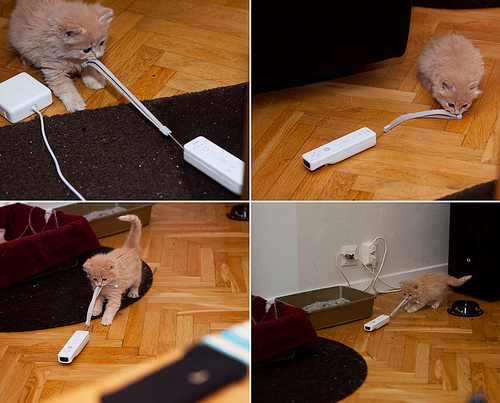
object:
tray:
[275, 285, 377, 329]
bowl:
[447, 300, 485, 318]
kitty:
[7, 0, 112, 113]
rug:
[0, 82, 249, 199]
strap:
[86, 285, 103, 326]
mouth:
[96, 284, 103, 288]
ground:
[249, 6, 499, 200]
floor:
[249, 5, 499, 200]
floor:
[315, 282, 500, 401]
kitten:
[83, 213, 142, 326]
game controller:
[302, 126, 376, 171]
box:
[248, 294, 318, 361]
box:
[0, 203, 101, 284]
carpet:
[0, 245, 154, 333]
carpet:
[252, 335, 370, 401]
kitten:
[417, 32, 484, 115]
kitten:
[399, 272, 473, 314]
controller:
[56, 329, 91, 366]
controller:
[364, 314, 391, 332]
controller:
[183, 135, 247, 195]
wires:
[370, 236, 402, 295]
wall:
[252, 206, 449, 300]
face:
[443, 91, 471, 111]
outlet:
[361, 242, 378, 266]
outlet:
[341, 244, 359, 266]